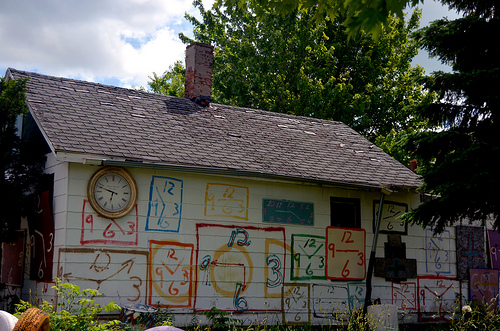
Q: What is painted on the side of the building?
A: Graffiti.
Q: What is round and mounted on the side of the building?
A: A clock.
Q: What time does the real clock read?
A: 6:45.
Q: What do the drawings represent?
A: Clocks.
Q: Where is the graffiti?
A: Side of house.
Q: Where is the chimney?
A: Middle of roof ridge.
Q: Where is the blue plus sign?
A: On the right.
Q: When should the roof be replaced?
A: Right away.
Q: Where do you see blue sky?
A: Around the trees.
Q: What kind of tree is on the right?
A: Evergreen.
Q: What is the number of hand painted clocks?
A: 16.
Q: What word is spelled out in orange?
A: God.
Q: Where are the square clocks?
A: On house.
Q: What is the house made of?
A: Wood.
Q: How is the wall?
A: Drawn.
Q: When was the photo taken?
A: Sunny day.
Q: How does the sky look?
A: Cloudy.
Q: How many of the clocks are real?
A: One.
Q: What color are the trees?
A: Green.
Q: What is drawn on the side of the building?
A: Clocks.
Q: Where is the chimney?
A: On the roof.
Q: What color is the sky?
A: Blue.